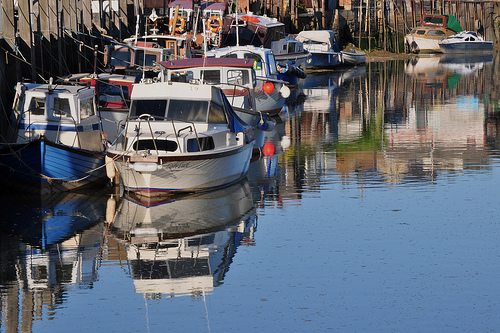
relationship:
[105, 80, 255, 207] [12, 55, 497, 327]
boat on water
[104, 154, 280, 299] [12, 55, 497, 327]
reflection on water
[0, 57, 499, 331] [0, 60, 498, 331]
calm water on lake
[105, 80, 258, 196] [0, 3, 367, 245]
boat on docks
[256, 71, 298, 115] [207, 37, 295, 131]
red light on boat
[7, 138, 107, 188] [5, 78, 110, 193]
hull on boat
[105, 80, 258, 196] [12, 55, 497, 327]
boat on water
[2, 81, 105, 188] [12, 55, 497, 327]
boat on water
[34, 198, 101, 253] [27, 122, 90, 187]
reflection on boat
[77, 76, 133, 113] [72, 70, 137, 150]
red trim on boat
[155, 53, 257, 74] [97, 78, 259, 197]
roof on boat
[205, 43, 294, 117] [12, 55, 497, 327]
boat lined up in water